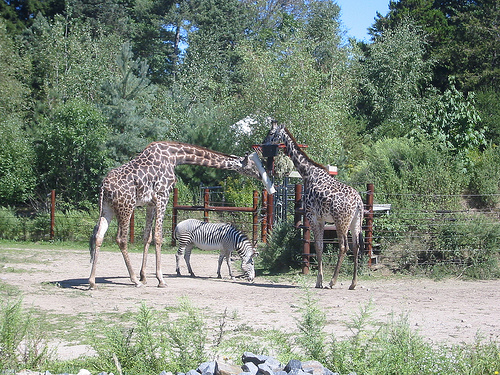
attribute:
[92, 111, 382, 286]
animals — plenty 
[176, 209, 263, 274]
zebra — black and white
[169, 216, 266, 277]
zebra — 2 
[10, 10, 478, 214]
trees — tall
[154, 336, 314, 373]
rocks — pile 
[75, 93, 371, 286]
giraffes — feeder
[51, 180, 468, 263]
fence — wire 